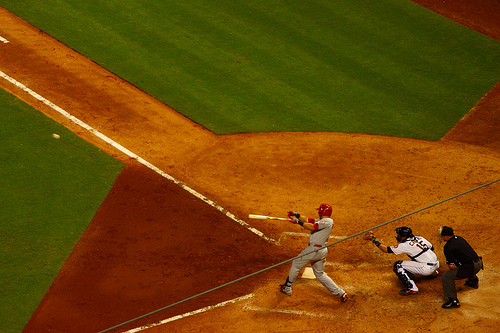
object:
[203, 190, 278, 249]
line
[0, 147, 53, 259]
grass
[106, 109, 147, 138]
dirt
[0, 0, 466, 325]
baseball field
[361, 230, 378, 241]
catcher's mitt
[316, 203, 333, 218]
helmet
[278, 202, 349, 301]
baseball batter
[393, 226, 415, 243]
helmet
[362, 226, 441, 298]
catcher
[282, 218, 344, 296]
uniform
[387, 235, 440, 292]
uniform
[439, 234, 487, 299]
uniform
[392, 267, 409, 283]
protector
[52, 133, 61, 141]
ball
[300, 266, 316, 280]
home plate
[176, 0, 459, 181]
grass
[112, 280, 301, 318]
chalk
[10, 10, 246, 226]
field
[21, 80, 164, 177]
stripes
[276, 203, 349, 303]
people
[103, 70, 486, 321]
game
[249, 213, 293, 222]
bat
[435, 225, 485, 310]
umpire